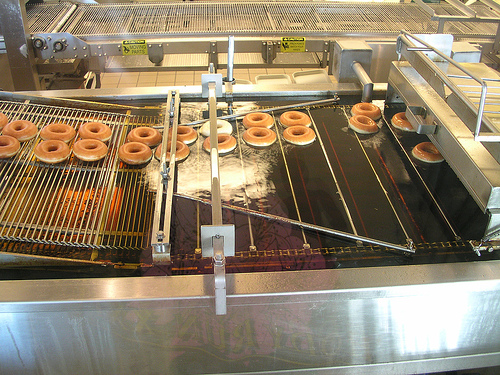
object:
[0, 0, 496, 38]
racks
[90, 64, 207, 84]
bad floor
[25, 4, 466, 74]
equipment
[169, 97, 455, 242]
donuts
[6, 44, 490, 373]
equipment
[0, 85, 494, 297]
belt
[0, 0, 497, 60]
belt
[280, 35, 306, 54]
sign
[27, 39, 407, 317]
oven